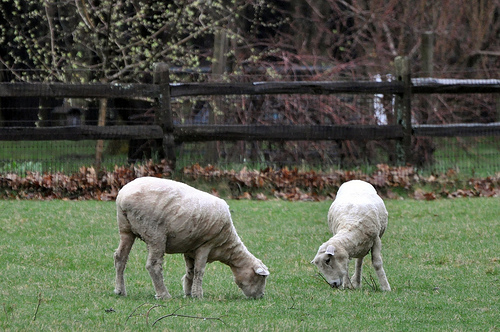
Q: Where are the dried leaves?
A: Along the sides of fence.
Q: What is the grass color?
A: Green.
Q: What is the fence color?
A: Grey.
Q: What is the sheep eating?
A: Grass.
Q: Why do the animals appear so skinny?
A: Their wool has been shorn.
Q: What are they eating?
A: Grass.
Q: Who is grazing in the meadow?
A: Two sheep.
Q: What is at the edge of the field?
A: A fence.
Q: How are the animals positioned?
A: Standing with their heads bent down.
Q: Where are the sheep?
A: In a field.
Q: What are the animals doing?
A: Grazing.